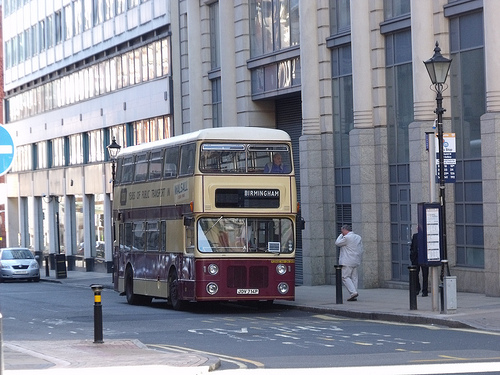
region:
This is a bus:
[109, 133, 309, 338]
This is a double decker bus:
[83, 121, 315, 348]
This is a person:
[333, 219, 365, 322]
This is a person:
[407, 218, 440, 322]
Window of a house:
[244, 60, 264, 97]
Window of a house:
[260, 60, 277, 94]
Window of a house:
[276, 60, 290, 87]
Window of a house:
[289, 53, 304, 92]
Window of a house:
[337, 41, 362, 86]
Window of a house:
[389, 24, 416, 69]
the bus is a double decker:
[50, 84, 415, 359]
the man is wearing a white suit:
[327, 202, 428, 369]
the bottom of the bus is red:
[179, 227, 343, 372]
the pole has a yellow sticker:
[77, 273, 135, 366]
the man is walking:
[314, 210, 381, 358]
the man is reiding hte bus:
[257, 144, 342, 261]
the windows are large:
[180, 200, 360, 326]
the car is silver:
[5, 229, 90, 319]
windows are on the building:
[17, 188, 189, 283]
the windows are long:
[12, 183, 237, 325]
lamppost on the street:
[422, 42, 461, 314]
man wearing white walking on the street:
[331, 218, 369, 302]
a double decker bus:
[107, 126, 300, 308]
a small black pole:
[91, 284, 109, 342]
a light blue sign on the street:
[0, 123, 17, 175]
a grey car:
[1, 247, 42, 282]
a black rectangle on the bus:
[213, 185, 282, 208]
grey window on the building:
[243, 41, 302, 100]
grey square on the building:
[120, 101, 129, 109]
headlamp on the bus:
[204, 259, 221, 277]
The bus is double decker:
[105, 123, 302, 313]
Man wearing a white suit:
[330, 220, 369, 304]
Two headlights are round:
[201, 278, 292, 299]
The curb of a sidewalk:
[269, 297, 477, 335]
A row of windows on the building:
[4, 38, 173, 123]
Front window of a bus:
[190, 211, 297, 259]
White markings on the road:
[184, 308, 469, 363]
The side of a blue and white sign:
[1, 122, 18, 178]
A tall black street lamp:
[422, 38, 456, 314]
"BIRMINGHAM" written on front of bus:
[241, 184, 284, 199]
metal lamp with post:
[419, 40, 463, 317]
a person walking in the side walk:
[336, 222, 379, 309]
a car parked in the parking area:
[2, 241, 41, 283]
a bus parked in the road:
[113, 148, 300, 310]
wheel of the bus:
[163, 265, 180, 311]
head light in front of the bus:
[208, 258, 293, 300]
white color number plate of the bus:
[233, 285, 263, 299]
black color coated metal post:
[430, 112, 452, 321]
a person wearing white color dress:
[337, 236, 363, 301]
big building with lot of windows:
[30, 18, 269, 118]